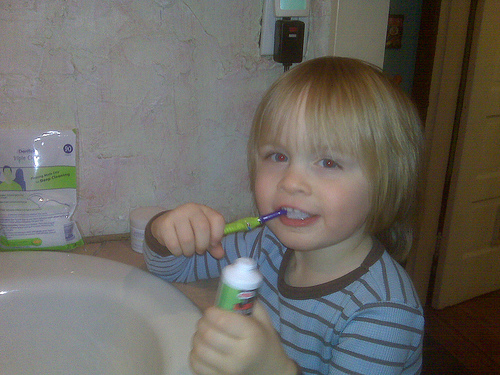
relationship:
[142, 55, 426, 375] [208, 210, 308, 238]
boy holding toothbrush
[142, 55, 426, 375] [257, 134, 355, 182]
boy has eyes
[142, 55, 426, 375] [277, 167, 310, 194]
boy has nose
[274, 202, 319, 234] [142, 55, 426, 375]
mouth of boy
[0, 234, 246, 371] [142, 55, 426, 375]
sink in front of boy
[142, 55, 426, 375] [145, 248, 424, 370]
boy wearing shirt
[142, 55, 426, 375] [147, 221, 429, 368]
boy wearing shirt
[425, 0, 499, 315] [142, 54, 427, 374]
door to right of child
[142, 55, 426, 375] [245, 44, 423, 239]
boy with hair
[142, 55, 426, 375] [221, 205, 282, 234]
boy holding toothbrush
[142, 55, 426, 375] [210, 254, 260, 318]
boy holding toothpaste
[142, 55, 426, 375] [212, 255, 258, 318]
boy holding tooth paste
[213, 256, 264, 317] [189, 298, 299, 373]
tooth paste in hand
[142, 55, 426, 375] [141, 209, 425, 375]
boy wearing shirt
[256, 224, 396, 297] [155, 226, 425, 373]
collar around shirt